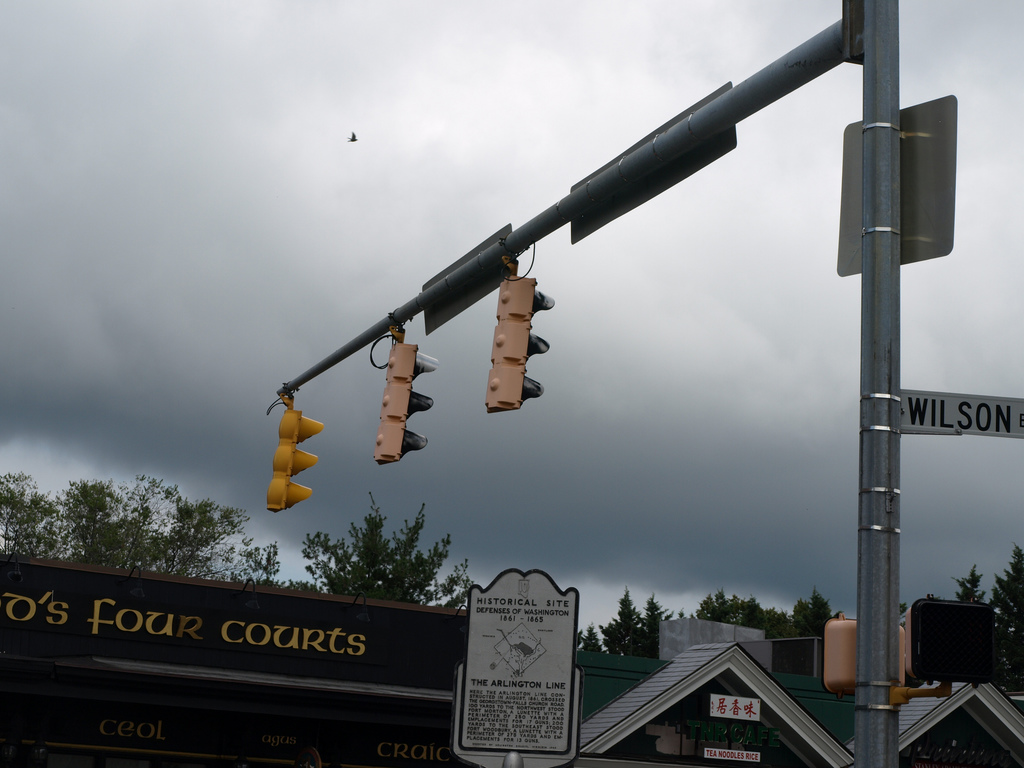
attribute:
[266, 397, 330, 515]
lights — yellow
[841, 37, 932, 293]
pole — metal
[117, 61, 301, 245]
sky — cloudy, grey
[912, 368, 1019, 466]
sign — white